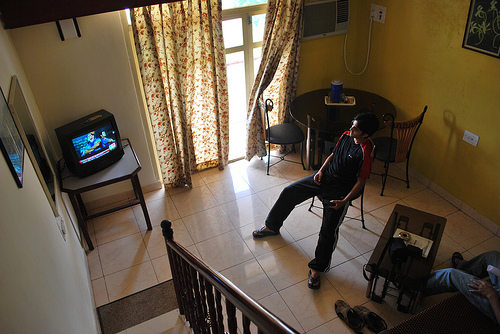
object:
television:
[54, 108, 125, 179]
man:
[252, 111, 379, 290]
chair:
[309, 140, 377, 227]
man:
[394, 249, 500, 321]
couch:
[372, 275, 499, 333]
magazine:
[392, 227, 432, 259]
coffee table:
[365, 202, 446, 314]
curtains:
[241, 0, 301, 162]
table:
[291, 87, 396, 173]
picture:
[0, 88, 26, 189]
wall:
[0, 21, 100, 334]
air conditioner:
[300, 2, 352, 41]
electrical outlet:
[369, 2, 389, 25]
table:
[56, 136, 153, 250]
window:
[124, 0, 268, 178]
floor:
[79, 144, 499, 334]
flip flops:
[305, 269, 322, 289]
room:
[0, 0, 499, 334]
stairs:
[115, 307, 201, 333]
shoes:
[333, 296, 366, 334]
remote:
[320, 199, 336, 208]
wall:
[295, 0, 356, 101]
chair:
[260, 98, 306, 176]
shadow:
[376, 102, 500, 243]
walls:
[366, 0, 498, 235]